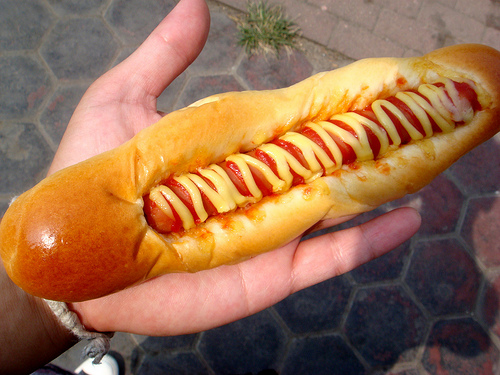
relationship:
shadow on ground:
[370, 321, 448, 352] [244, 2, 375, 53]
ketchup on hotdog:
[226, 161, 238, 174] [147, 114, 484, 212]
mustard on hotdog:
[213, 187, 242, 206] [157, 128, 442, 195]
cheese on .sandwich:
[199, 164, 253, 212] [0, 42, 499, 303]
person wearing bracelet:
[4, 6, 426, 335] [47, 300, 111, 370]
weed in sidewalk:
[229, 5, 311, 54] [284, 4, 462, 44]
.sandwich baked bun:
[0, 42, 499, 303] [20, 188, 122, 293]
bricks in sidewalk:
[351, 290, 425, 354] [324, 12, 463, 38]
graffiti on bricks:
[434, 262, 484, 361] [280, 331, 362, 362]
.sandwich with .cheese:
[16, 45, 471, 262] [171, 170, 249, 214]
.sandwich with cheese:
[0, 42, 499, 303] [155, 87, 467, 215]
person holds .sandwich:
[0, 0, 427, 374] [0, 42, 499, 303]